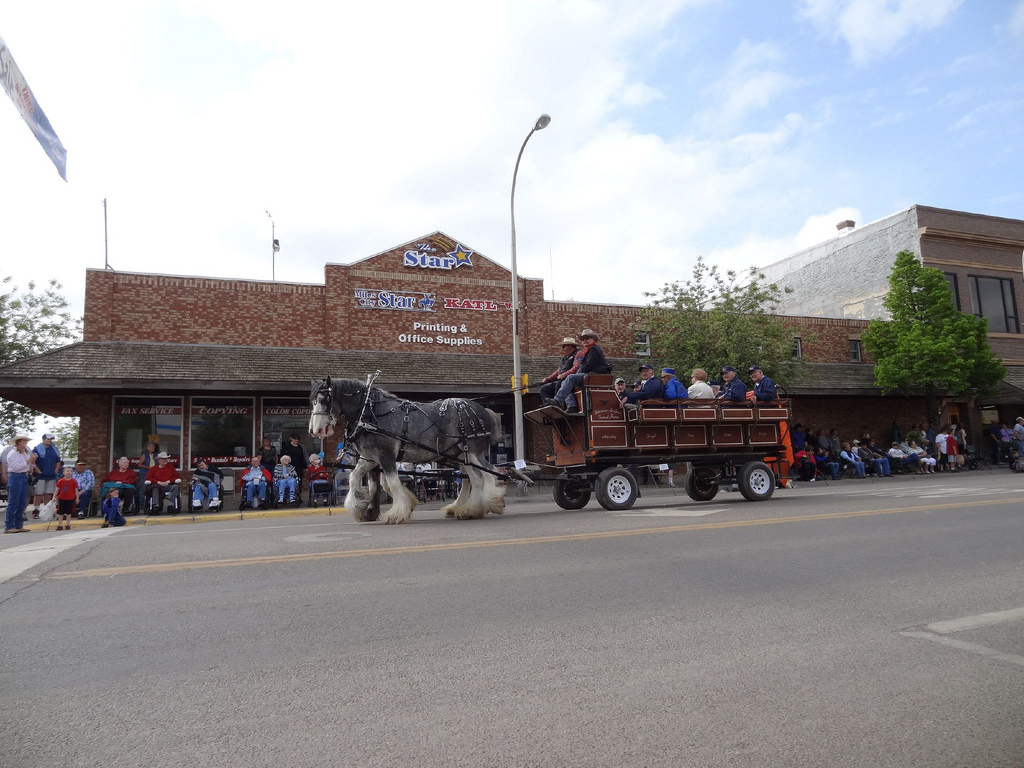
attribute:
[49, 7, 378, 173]
clouds — white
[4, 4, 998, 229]
sky — blue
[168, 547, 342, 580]
line — yellow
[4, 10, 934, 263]
clouds — white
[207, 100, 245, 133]
clouds — white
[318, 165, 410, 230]
clouds — white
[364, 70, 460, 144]
clouds — white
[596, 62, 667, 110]
clouds — white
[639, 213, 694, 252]
clouds — white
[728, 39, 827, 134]
clouds — white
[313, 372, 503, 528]
horse — gray, white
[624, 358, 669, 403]
person — blue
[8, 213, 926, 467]
building — red brick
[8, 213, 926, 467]
sign — star 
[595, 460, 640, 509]
wheel — white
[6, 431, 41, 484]
shirt — white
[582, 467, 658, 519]
tire — black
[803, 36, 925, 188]
sky — blue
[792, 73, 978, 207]
sky — blue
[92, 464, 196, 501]
shirt — red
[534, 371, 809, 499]
wagon — brown 